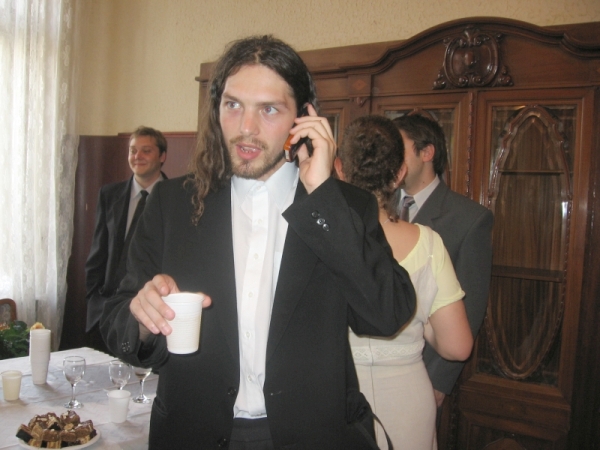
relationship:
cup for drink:
[160, 292, 201, 355] [156, 281, 208, 366]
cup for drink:
[160, 292, 201, 355] [158, 285, 214, 313]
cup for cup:
[160, 292, 201, 355] [160, 292, 201, 355]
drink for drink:
[107, 389, 131, 424] [101, 385, 133, 409]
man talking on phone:
[98, 34, 417, 450] [283, 106, 312, 149]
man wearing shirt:
[98, 34, 417, 450] [225, 161, 293, 440]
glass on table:
[59, 352, 89, 417] [13, 336, 152, 448]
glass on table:
[105, 349, 129, 397] [13, 336, 152, 448]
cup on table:
[3, 365, 25, 404] [13, 342, 167, 442]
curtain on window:
[4, 1, 83, 307] [5, 2, 53, 304]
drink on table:
[107, 389, 131, 424] [2, 340, 162, 447]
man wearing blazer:
[98, 34, 417, 450] [100, 171, 419, 450]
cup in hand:
[156, 288, 200, 357] [127, 272, 217, 339]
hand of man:
[127, 272, 217, 339] [98, 34, 417, 450]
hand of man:
[281, 101, 342, 192] [92, 25, 440, 441]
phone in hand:
[289, 104, 302, 170] [281, 101, 342, 192]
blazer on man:
[103, 168, 419, 446] [92, 25, 440, 441]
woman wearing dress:
[331, 114, 477, 445] [350, 226, 460, 444]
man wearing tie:
[84, 124, 169, 331] [118, 188, 152, 251]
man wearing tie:
[88, 126, 177, 331] [119, 184, 149, 239]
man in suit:
[88, 126, 177, 331] [80, 180, 167, 373]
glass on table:
[109, 361, 132, 390] [2, 346, 172, 447]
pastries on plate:
[15, 409, 98, 449] [4, 409, 91, 448]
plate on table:
[4, 409, 91, 448] [2, 339, 187, 446]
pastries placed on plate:
[15, 407, 94, 441] [13, 424, 98, 448]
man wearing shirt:
[92, 25, 440, 441] [225, 161, 293, 440]